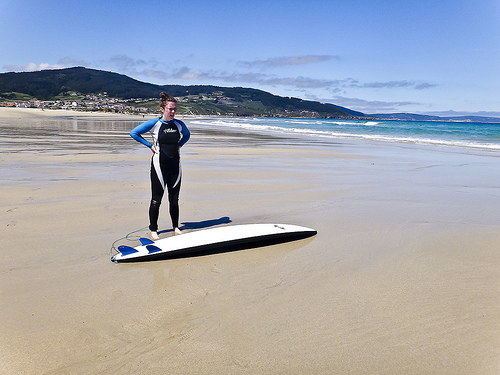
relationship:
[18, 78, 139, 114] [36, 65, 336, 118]
village near mountains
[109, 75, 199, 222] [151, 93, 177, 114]
woman has hair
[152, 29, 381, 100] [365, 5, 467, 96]
clouds in sky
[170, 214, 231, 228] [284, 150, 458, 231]
shadow on beach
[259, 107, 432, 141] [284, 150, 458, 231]
waves near beach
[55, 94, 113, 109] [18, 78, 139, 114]
buildings in village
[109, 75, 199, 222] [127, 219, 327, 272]
woman near board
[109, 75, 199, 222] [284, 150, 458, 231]
woman on beach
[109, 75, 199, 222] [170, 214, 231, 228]
woman has shadow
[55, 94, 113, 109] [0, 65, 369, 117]
buildings on mountains